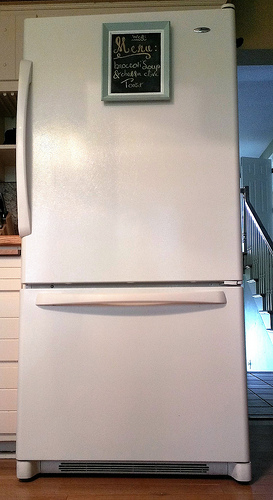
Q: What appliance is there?
A: Refrigerator.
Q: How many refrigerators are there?
A: One.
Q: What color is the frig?
A: White.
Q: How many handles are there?
A: Two.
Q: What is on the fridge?
A: Chalkboard.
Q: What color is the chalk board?
A: Black.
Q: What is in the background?
A: Stairs.